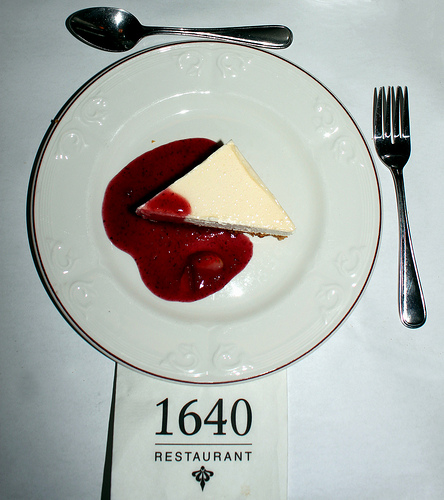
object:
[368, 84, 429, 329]
fork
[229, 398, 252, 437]
number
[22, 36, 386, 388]
plate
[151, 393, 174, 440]
number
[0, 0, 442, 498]
tablecloth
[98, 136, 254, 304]
strawberry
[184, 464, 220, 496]
emblem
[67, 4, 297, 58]
spoon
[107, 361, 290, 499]
paper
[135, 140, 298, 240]
dessert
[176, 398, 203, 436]
six